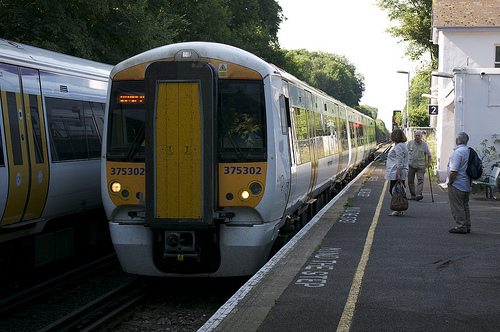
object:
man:
[441, 130, 479, 234]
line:
[333, 173, 391, 332]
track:
[428, 103, 437, 117]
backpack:
[390, 175, 410, 213]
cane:
[424, 165, 434, 205]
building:
[432, 1, 500, 184]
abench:
[472, 166, 497, 201]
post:
[403, 76, 410, 135]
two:
[0, 39, 378, 276]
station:
[188, 104, 500, 332]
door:
[145, 79, 213, 272]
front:
[102, 50, 269, 211]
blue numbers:
[222, 166, 263, 176]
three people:
[384, 129, 484, 234]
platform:
[195, 144, 500, 298]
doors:
[2, 91, 52, 228]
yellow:
[13, 183, 21, 212]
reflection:
[216, 85, 262, 162]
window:
[212, 99, 267, 164]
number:
[428, 105, 442, 115]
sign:
[425, 101, 440, 117]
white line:
[191, 158, 375, 332]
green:
[268, 50, 361, 82]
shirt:
[384, 141, 410, 181]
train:
[100, 42, 376, 278]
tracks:
[4, 140, 295, 242]